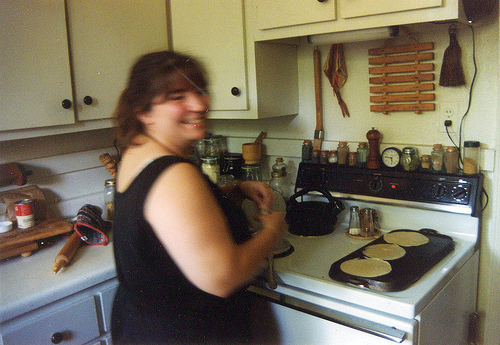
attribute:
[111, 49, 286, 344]
woman — clothed, smiling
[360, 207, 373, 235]
shaker — brown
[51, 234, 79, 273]
pin — wooden, brown, long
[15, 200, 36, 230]
can — red, round, small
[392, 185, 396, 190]
light — lit, off, red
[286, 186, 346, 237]
kettle — black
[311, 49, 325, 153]
brush — hanging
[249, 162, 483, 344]
stove — white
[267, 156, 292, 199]
jar — glass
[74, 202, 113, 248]
mitt — red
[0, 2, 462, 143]
cupboards — white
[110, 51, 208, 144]
hair — brown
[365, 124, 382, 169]
grinder — wooden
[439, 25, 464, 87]
broom — dark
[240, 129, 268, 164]
pestle — brown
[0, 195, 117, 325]
counter — white